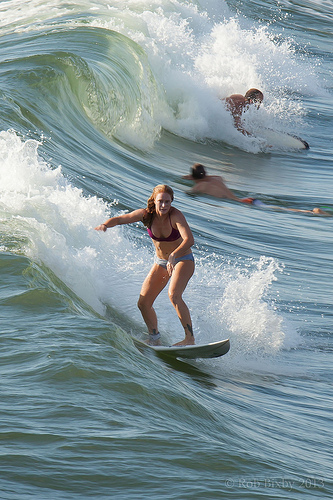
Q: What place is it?
A: It is an ocean.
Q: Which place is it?
A: It is an ocean.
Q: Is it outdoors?
A: Yes, it is outdoors.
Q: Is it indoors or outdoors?
A: It is outdoors.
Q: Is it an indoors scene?
A: No, it is outdoors.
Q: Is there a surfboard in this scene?
A: Yes, there is a surfboard.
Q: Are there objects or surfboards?
A: Yes, there is a surfboard.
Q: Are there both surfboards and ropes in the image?
A: No, there is a surfboard but no ropes.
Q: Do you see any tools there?
A: No, there are no tools.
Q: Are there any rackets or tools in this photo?
A: No, there are no tools or rackets.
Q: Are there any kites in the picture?
A: No, there are no kites.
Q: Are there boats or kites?
A: No, there are no kites or boats.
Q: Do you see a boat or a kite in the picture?
A: No, there are no kites or boats.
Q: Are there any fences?
A: No, there are no fences.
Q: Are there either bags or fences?
A: No, there are no fences or bags.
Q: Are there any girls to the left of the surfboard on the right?
A: Yes, there is a girl to the left of the surf board.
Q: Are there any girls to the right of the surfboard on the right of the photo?
A: No, the girl is to the left of the surfboard.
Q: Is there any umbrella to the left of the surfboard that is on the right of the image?
A: No, there is a girl to the left of the surfboard.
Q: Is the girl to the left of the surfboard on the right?
A: Yes, the girl is to the left of the surfboard.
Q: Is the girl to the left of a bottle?
A: No, the girl is to the left of the surfboard.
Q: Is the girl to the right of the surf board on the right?
A: No, the girl is to the left of the surfboard.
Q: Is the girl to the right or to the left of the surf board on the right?
A: The girl is to the left of the surf board.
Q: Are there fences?
A: No, there are no fences.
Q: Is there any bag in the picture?
A: No, there are no bags.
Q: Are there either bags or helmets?
A: No, there are no bags or helmets.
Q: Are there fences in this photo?
A: No, there are no fences.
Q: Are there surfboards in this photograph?
A: Yes, there is a surfboard.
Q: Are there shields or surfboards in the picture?
A: Yes, there is a surfboard.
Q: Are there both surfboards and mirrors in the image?
A: No, there is a surfboard but no mirrors.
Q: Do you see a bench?
A: No, there are no benches.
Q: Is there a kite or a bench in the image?
A: No, there are no benches or kites.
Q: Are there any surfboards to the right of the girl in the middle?
A: Yes, there is a surfboard to the right of the girl.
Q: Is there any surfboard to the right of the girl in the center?
A: Yes, there is a surfboard to the right of the girl.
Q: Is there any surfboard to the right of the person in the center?
A: Yes, there is a surfboard to the right of the girl.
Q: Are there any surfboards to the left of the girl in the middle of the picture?
A: No, the surfboard is to the right of the girl.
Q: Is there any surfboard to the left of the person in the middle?
A: No, the surfboard is to the right of the girl.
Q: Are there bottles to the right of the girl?
A: No, there is a surfboard to the right of the girl.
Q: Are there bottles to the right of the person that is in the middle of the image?
A: No, there is a surfboard to the right of the girl.